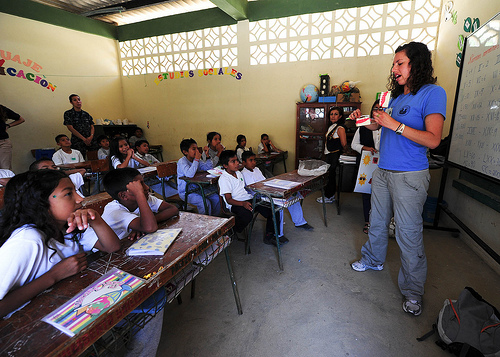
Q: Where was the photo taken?
A: In a classroom.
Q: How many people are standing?
A: Four.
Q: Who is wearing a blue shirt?
A: The teacher.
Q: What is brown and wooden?
A: The desks.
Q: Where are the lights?
A: On the ceiling.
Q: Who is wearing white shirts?
A: Students.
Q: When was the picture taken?
A: Daytime.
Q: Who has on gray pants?
A: Teacher.